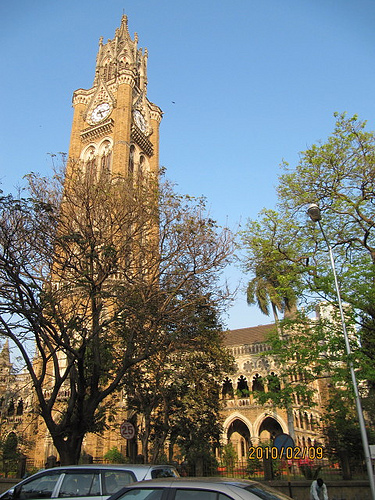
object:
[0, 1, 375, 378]
blue sky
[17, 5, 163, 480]
tower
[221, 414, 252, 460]
arches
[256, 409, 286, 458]
arches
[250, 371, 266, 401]
arches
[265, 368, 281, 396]
arches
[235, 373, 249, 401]
arches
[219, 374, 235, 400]
arches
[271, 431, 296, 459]
sign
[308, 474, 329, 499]
man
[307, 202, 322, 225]
street lamp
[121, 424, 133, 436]
number 25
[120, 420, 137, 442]
sign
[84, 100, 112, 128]
clock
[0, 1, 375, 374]
clouds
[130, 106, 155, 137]
clock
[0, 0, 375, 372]
sky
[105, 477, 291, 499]
car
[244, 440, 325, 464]
date stamp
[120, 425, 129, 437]
number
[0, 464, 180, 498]
hatchback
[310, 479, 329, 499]
shirt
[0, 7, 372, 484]
building